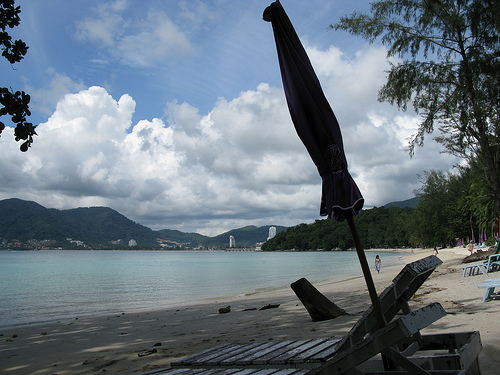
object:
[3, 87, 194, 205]
cloud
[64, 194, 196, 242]
plate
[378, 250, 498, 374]
sand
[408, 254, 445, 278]
handle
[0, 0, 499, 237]
sky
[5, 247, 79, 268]
water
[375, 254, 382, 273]
people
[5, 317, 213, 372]
beach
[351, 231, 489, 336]
beach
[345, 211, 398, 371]
handle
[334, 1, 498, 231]
tree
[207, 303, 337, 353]
sand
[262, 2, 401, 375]
umbrella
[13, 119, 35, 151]
leaves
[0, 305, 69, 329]
water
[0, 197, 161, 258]
mountain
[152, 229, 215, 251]
hill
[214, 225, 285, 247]
hill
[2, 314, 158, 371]
sand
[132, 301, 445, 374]
chair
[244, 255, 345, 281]
water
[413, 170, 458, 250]
trees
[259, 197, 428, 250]
mountain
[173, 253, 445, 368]
chair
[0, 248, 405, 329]
ocean